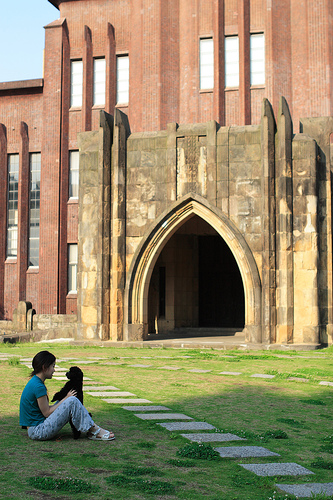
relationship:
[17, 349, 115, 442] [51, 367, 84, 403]
girl holding dog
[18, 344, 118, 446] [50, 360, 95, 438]
girl holding dog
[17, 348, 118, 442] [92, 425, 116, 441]
she wearing sandals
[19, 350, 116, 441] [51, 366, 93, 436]
woman holding dog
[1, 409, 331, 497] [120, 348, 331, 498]
shadow on grass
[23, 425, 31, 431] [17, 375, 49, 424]
skin exposed underneath shirt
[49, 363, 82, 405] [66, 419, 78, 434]
dog on legs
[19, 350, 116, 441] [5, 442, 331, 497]
woman sitting in grass